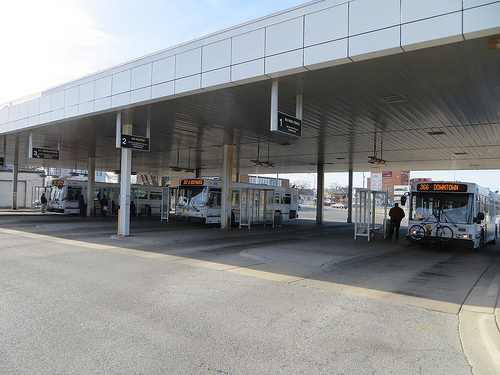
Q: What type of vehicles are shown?
A: Buses.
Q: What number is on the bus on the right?
A: 306.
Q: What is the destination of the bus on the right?
A: Downtown.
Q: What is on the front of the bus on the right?
A: Bicycle.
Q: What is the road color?
A: Grey.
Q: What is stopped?
A: Bus.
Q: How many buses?
A: Three.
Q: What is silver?
A: Awning.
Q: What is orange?
A: Letters.